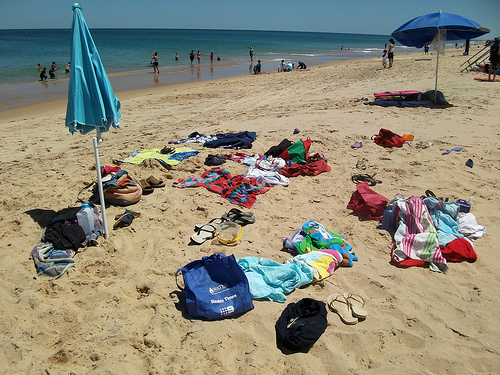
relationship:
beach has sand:
[18, 69, 497, 369] [1, 40, 495, 372]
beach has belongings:
[18, 69, 497, 369] [245, 135, 330, 190]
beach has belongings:
[18, 69, 497, 369] [376, 187, 486, 273]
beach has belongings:
[18, 69, 497, 369] [31, 198, 103, 277]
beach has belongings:
[18, 69, 497, 369] [170, 130, 256, 151]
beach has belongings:
[18, 69, 497, 369] [91, 162, 166, 207]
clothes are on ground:
[234, 252, 317, 304] [106, 202, 171, 357]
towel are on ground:
[387, 191, 449, 274] [106, 202, 171, 357]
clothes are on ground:
[283, 244, 343, 284] [106, 202, 171, 357]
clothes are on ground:
[173, 171, 258, 207] [106, 202, 171, 357]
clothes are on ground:
[243, 161, 294, 189] [106, 202, 171, 357]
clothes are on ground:
[225, 148, 289, 173] [106, 202, 171, 357]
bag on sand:
[168, 248, 262, 326] [30, 305, 148, 372]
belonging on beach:
[26, 200, 91, 250] [18, 69, 497, 369]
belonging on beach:
[273, 290, 333, 359] [18, 69, 497, 369]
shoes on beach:
[327, 293, 361, 325] [18, 69, 497, 369]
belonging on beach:
[190, 214, 220, 247] [18, 69, 497, 369]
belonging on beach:
[280, 157, 331, 178] [18, 69, 497, 369]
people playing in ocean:
[26, 41, 61, 95] [1, 22, 431, 109]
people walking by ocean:
[135, 38, 260, 75] [12, 28, 375, 115]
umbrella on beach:
[392, 10, 489, 94] [213, 67, 492, 188]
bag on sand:
[343, 180, 388, 222] [1, 40, 495, 372]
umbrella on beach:
[392, 10, 489, 94] [454, 81, 481, 113]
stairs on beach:
[456, 41, 493, 77] [4, 43, 497, 370]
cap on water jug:
[82, 201, 90, 210] [74, 199, 99, 234]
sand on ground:
[45, 296, 177, 373] [449, 114, 493, 141]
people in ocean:
[25, 36, 407, 88] [0, 28, 492, 115]